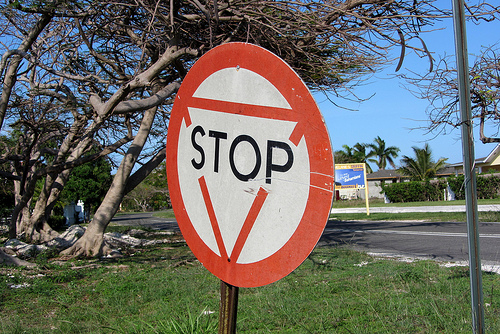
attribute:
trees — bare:
[4, 3, 494, 271]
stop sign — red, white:
[156, 34, 341, 295]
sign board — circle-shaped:
[163, 40, 336, 287]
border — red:
[162, 38, 335, 288]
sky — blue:
[1, 1, 482, 172]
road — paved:
[110, 209, 485, 265]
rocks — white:
[15, 231, 81, 269]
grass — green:
[205, 257, 350, 327]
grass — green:
[298, 256, 423, 311]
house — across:
[363, 139, 478, 213]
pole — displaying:
[200, 275, 253, 322]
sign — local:
[311, 147, 395, 242]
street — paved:
[135, 205, 488, 261]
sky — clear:
[306, 41, 470, 168]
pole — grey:
[446, 0, 484, 332]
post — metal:
[215, 280, 242, 327]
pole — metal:
[352, 184, 361, 200]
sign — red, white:
[155, 36, 374, 272]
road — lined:
[328, 205, 497, 247]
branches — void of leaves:
[302, 2, 401, 76]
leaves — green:
[411, 147, 431, 168]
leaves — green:
[366, 150, 379, 159]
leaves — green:
[361, 140, 377, 151]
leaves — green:
[70, 173, 90, 194]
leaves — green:
[422, 152, 430, 174]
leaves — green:
[1, 172, 11, 191]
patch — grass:
[403, 283, 449, 323]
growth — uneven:
[422, 297, 453, 319]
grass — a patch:
[308, 287, 376, 332]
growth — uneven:
[330, 296, 354, 319]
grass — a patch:
[259, 290, 335, 330]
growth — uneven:
[306, 290, 326, 312]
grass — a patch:
[325, 265, 462, 332]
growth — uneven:
[379, 296, 415, 318]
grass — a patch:
[44, 269, 160, 332]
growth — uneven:
[77, 289, 112, 321]